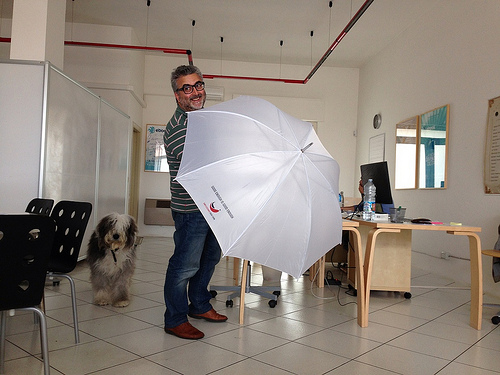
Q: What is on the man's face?
A: Glasses.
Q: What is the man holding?
A: An umbrella.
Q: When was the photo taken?
A: Day time.